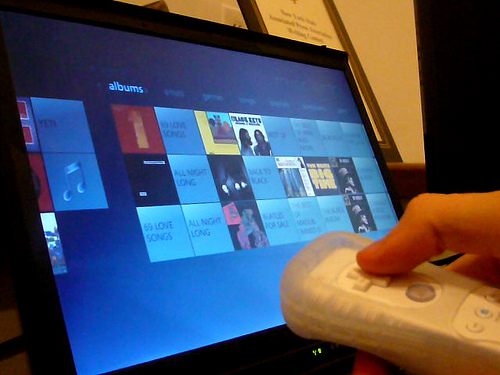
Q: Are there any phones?
A: No, there are no phones.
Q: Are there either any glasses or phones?
A: No, there are no phones or glasses.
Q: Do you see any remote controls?
A: Yes, there is a remote control.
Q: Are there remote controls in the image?
A: Yes, there is a remote control.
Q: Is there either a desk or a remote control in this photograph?
A: Yes, there is a remote control.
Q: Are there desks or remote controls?
A: Yes, there is a remote control.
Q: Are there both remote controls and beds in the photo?
A: No, there is a remote control but no beds.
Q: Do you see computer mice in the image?
A: No, there are no computer mice.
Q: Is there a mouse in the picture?
A: No, there are no computer mice.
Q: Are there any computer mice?
A: No, there are no computer mice.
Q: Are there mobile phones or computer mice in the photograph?
A: No, there are no computer mice or mobile phones.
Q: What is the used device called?
A: The device is a remote control.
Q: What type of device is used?
A: The device is a remote control.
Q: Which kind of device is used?
A: The device is a remote control.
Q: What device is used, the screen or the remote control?
A: The remote control is used.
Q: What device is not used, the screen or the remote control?
A: The screen is not used.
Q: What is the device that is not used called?
A: The device is a screen.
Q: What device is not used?
A: The device is a screen.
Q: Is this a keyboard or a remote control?
A: This is a remote control.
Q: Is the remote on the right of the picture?
A: Yes, the remote is on the right of the image.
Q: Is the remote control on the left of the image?
A: No, the remote control is on the right of the image.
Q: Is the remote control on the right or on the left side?
A: The remote control is on the right of the image.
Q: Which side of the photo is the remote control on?
A: The remote control is on the right of the image.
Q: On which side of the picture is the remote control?
A: The remote control is on the right of the image.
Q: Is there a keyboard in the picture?
A: No, there are no keyboards.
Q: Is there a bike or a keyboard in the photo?
A: No, there are no keyboards or bikes.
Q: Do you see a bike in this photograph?
A: No, there are no bikes.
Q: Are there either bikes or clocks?
A: No, there are no bikes or clocks.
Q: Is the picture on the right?
A: Yes, the picture is on the right of the image.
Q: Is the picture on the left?
A: No, the picture is on the right of the image.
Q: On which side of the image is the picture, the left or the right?
A: The picture is on the right of the image.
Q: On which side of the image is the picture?
A: The picture is on the right of the image.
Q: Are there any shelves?
A: No, there are no shelves.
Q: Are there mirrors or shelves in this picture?
A: No, there are no shelves or mirrors.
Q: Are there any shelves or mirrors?
A: No, there are no shelves or mirrors.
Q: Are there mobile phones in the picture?
A: No, there are no mobile phones.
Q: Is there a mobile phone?
A: No, there are no cell phones.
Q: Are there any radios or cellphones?
A: No, there are no cellphones or radios.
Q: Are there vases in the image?
A: No, there are no vases.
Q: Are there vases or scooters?
A: No, there are no vases or scooters.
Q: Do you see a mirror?
A: No, there are no mirrors.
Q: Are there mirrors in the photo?
A: No, there are no mirrors.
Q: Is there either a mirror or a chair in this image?
A: No, there are no mirrors or chairs.